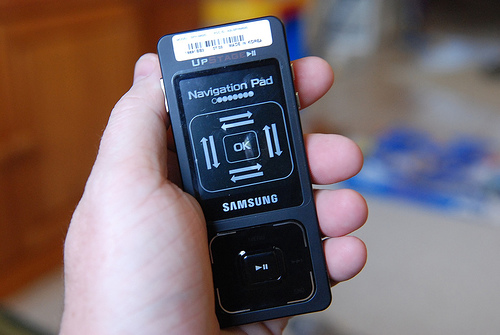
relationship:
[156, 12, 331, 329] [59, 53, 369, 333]
cell phone held in hand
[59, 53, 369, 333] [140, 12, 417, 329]
hand holding phone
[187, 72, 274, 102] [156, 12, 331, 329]
navigation pad on cell phone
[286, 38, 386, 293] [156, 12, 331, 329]
finger holding cell phone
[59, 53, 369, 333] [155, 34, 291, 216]
hand holding cell phone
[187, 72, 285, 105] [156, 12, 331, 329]
navigation pad on cell phone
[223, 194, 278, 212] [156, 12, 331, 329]
samsung printed across cell phone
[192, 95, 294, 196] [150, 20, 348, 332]
track pad on phone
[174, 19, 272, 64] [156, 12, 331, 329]
sticker on cell phone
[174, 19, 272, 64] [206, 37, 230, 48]
sticker with barcode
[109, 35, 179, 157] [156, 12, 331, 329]
thumb against side of cell phone